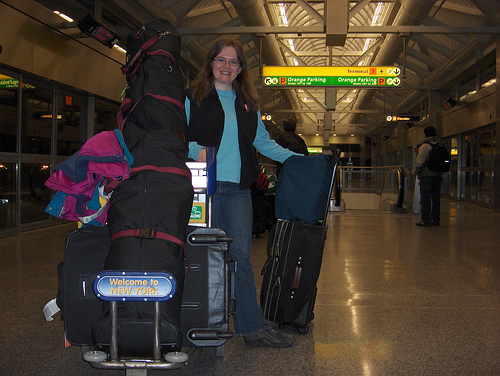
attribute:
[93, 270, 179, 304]
sign — low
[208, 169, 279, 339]
jeans — blue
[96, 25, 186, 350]
bag — long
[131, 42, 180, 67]
strap — red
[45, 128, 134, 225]
coat — pink and green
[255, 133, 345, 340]
bag — traveling bag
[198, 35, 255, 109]
hair — light brown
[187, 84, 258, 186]
vest — black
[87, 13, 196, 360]
bag — black, long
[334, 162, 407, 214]
escalator — top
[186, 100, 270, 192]
shirt — blue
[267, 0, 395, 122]
lights — bright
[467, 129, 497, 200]
door — part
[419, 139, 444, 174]
backpack — black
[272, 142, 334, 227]
bag — blue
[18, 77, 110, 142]
grass windows — framed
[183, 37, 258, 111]
hair — brown, long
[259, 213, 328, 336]
suitcase — black